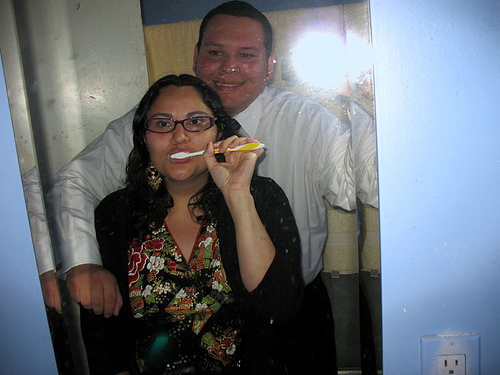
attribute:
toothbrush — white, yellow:
[164, 136, 306, 183]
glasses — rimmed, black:
[154, 106, 270, 150]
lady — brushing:
[102, 74, 289, 294]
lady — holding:
[64, 87, 276, 373]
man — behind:
[207, 33, 355, 229]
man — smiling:
[172, 16, 374, 196]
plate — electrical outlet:
[407, 325, 488, 371]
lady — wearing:
[113, 90, 290, 329]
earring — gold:
[138, 150, 182, 192]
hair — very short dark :
[199, 8, 279, 50]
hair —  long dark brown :
[124, 82, 251, 224]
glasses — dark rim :
[135, 109, 219, 138]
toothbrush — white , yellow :
[169, 136, 269, 159]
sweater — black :
[60, 178, 325, 364]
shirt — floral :
[117, 218, 239, 361]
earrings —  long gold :
[144, 165, 159, 186]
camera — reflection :
[69, 8, 359, 348]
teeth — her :
[163, 151, 197, 163]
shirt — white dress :
[56, 80, 370, 272]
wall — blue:
[380, 10, 483, 367]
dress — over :
[109, 216, 284, 373]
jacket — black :
[91, 164, 307, 364]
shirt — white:
[66, 89, 373, 286]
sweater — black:
[84, 173, 309, 369]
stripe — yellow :
[224, 140, 264, 153]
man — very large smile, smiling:
[51, 9, 384, 371]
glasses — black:
[144, 110, 219, 137]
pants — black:
[288, 278, 353, 370]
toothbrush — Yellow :
[173, 138, 268, 166]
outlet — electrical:
[433, 351, 477, 372]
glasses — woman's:
[140, 110, 218, 139]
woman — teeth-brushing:
[72, 71, 326, 361]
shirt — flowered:
[118, 213, 249, 357]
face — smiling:
[193, 19, 266, 111]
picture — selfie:
[43, 5, 374, 355]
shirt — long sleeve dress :
[44, 84, 356, 281]